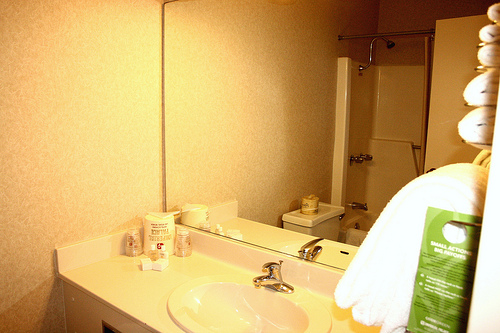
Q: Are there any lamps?
A: No, there are no lamps.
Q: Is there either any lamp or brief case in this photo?
A: No, there are no lamps or briefcases.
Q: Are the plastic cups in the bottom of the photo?
A: Yes, the cups are in the bottom of the image.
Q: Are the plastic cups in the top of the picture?
A: No, the cups are in the bottom of the image.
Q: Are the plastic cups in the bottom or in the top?
A: The cups are in the bottom of the image.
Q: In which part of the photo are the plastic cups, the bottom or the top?
A: The cups are in the bottom of the image.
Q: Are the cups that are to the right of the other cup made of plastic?
A: Yes, the cups are made of plastic.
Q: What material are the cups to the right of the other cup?
A: The cups are made of plastic.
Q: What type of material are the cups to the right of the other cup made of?
A: The cups are made of plastic.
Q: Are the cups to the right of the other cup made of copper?
A: No, the cups are made of plastic.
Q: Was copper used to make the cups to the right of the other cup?
A: No, the cups are made of plastic.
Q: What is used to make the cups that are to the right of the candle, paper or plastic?
A: The cups are made of plastic.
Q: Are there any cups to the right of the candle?
A: Yes, there are cups to the right of the candle.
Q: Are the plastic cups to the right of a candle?
A: Yes, the cups are to the right of a candle.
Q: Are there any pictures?
A: No, there are no pictures.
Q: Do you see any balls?
A: No, there are no balls.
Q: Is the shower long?
A: Yes, the shower is long.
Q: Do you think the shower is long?
A: Yes, the shower is long.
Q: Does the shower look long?
A: Yes, the shower is long.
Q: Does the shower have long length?
A: Yes, the shower is long.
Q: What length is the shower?
A: The shower is long.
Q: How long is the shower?
A: The shower is long.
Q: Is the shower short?
A: No, the shower is long.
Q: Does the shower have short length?
A: No, the shower is long.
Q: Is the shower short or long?
A: The shower is long.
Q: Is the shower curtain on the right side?
A: Yes, the shower curtain is on the right of the image.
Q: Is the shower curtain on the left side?
A: No, the shower curtain is on the right of the image.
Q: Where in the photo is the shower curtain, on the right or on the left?
A: The shower curtain is on the right of the image.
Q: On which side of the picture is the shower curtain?
A: The shower curtain is on the right of the image.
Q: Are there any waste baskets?
A: No, there are no waste baskets.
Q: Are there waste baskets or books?
A: No, there are no waste baskets or books.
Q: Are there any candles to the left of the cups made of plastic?
A: Yes, there is a candle to the left of the cups.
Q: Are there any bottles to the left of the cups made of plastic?
A: No, there is a candle to the left of the cups.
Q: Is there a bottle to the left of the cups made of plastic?
A: No, there is a candle to the left of the cups.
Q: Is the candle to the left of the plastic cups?
A: Yes, the candle is to the left of the cups.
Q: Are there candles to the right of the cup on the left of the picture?
A: Yes, there is a candle to the right of the cup.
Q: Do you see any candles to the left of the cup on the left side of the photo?
A: No, the candle is to the right of the cup.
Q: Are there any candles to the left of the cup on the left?
A: No, the candle is to the right of the cup.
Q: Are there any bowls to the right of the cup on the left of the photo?
A: No, there is a candle to the right of the cup.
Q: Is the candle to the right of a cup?
A: Yes, the candle is to the right of a cup.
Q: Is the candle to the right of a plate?
A: No, the candle is to the right of a cup.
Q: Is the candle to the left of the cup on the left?
A: No, the candle is to the right of the cup.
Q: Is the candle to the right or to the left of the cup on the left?
A: The candle is to the right of the cup.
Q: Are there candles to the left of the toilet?
A: Yes, there is a candle to the left of the toilet.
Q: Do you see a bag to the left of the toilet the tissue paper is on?
A: No, there is a candle to the left of the toilet.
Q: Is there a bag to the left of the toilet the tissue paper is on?
A: No, there is a candle to the left of the toilet.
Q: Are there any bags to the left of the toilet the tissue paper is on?
A: No, there is a candle to the left of the toilet.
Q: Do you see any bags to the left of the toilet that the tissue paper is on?
A: No, there is a candle to the left of the toilet.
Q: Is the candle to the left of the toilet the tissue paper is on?
A: Yes, the candle is to the left of the toilet.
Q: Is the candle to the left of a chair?
A: No, the candle is to the left of the toilet.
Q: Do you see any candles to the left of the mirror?
A: Yes, there is a candle to the left of the mirror.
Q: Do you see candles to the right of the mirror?
A: No, the candle is to the left of the mirror.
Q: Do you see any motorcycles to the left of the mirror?
A: No, there is a candle to the left of the mirror.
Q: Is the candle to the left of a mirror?
A: Yes, the candle is to the left of a mirror.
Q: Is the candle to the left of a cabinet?
A: No, the candle is to the left of a mirror.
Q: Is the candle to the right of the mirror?
A: No, the candle is to the left of the mirror.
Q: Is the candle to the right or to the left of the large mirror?
A: The candle is to the left of the mirror.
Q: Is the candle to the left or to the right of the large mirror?
A: The candle is to the left of the mirror.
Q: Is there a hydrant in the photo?
A: No, there are no fire hydrants.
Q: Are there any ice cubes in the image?
A: No, there are no ice cubes.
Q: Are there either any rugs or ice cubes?
A: No, there are no ice cubes or rugs.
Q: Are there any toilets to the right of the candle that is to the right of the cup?
A: Yes, there is a toilet to the right of the candle.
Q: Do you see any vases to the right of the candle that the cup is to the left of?
A: No, there is a toilet to the right of the candle.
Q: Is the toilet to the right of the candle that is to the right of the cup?
A: Yes, the toilet is to the right of the candle.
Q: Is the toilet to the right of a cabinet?
A: No, the toilet is to the right of the candle.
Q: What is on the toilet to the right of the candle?
A: The tissue paper is on the toilet.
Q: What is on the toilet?
A: The tissue paper is on the toilet.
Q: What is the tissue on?
A: The tissue is on the toilet.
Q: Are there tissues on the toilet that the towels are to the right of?
A: Yes, there is a tissue on the toilet.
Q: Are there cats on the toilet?
A: No, there is a tissue on the toilet.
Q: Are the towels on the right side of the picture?
A: Yes, the towels are on the right of the image.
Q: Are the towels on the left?
A: No, the towels are on the right of the image.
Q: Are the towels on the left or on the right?
A: The towels are on the right of the image.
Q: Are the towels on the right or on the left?
A: The towels are on the right of the image.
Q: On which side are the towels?
A: The towels are on the right of the image.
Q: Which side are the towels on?
A: The towels are on the right of the image.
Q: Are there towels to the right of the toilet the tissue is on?
A: Yes, there are towels to the right of the toilet.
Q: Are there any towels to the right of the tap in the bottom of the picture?
A: Yes, there are towels to the right of the tap.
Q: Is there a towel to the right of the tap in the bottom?
A: Yes, there are towels to the right of the tap.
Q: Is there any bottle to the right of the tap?
A: No, there are towels to the right of the tap.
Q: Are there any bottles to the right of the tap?
A: No, there are towels to the right of the tap.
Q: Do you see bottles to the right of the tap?
A: No, there are towels to the right of the tap.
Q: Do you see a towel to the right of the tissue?
A: Yes, there are towels to the right of the tissue.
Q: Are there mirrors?
A: Yes, there is a mirror.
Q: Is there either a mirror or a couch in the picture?
A: Yes, there is a mirror.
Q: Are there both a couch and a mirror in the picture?
A: No, there is a mirror but no couches.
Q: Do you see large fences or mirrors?
A: Yes, there is a large mirror.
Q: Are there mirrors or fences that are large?
A: Yes, the mirror is large.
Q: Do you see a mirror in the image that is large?
A: Yes, there is a large mirror.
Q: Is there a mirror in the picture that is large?
A: Yes, there is a mirror that is large.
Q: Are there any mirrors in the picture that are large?
A: Yes, there is a mirror that is large.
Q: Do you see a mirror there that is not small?
A: Yes, there is a large mirror.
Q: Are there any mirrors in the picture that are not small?
A: Yes, there is a large mirror.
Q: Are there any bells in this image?
A: No, there are no bells.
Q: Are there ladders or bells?
A: No, there are no bells or ladders.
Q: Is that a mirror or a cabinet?
A: That is a mirror.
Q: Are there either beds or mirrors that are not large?
A: No, there is a mirror but it is large.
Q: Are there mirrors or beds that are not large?
A: No, there is a mirror but it is large.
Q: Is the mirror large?
A: Yes, the mirror is large.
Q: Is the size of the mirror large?
A: Yes, the mirror is large.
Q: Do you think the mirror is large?
A: Yes, the mirror is large.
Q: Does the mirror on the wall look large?
A: Yes, the mirror is large.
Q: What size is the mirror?
A: The mirror is large.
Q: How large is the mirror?
A: The mirror is large.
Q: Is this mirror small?
A: No, the mirror is large.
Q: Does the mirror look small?
A: No, the mirror is large.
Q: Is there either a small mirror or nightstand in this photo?
A: No, there is a mirror but it is large.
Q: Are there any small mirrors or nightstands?
A: No, there is a mirror but it is large.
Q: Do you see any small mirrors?
A: No, there is a mirror but it is large.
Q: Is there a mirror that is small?
A: No, there is a mirror but it is large.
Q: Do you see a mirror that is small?
A: No, there is a mirror but it is large.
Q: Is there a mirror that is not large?
A: No, there is a mirror but it is large.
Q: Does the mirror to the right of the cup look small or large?
A: The mirror is large.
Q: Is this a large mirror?
A: Yes, this is a large mirror.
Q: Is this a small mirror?
A: No, this is a large mirror.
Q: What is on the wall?
A: The mirror is on the wall.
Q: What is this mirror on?
A: The mirror is on the wall.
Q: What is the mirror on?
A: The mirror is on the wall.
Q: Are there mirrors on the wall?
A: Yes, there is a mirror on the wall.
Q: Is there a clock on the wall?
A: No, there is a mirror on the wall.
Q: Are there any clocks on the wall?
A: No, there is a mirror on the wall.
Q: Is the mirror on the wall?
A: Yes, the mirror is on the wall.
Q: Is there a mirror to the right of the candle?
A: Yes, there is a mirror to the right of the candle.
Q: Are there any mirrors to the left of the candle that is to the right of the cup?
A: No, the mirror is to the right of the candle.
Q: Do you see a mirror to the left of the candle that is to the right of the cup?
A: No, the mirror is to the right of the candle.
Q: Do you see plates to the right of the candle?
A: No, there is a mirror to the right of the candle.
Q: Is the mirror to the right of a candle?
A: Yes, the mirror is to the right of a candle.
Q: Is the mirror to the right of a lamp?
A: No, the mirror is to the right of a candle.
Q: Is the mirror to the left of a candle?
A: No, the mirror is to the right of a candle.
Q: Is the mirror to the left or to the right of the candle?
A: The mirror is to the right of the candle.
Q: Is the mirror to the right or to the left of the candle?
A: The mirror is to the right of the candle.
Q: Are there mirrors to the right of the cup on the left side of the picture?
A: Yes, there is a mirror to the right of the cup.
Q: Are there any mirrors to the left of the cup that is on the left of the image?
A: No, the mirror is to the right of the cup.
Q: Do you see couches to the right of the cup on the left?
A: No, there is a mirror to the right of the cup.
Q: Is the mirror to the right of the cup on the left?
A: Yes, the mirror is to the right of the cup.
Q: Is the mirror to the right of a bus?
A: No, the mirror is to the right of the cup.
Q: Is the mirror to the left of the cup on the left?
A: No, the mirror is to the right of the cup.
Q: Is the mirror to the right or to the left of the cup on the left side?
A: The mirror is to the right of the cup.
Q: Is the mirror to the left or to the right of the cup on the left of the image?
A: The mirror is to the right of the cup.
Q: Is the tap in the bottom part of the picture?
A: Yes, the tap is in the bottom of the image.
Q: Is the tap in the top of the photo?
A: No, the tap is in the bottom of the image.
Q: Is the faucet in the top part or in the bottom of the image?
A: The faucet is in the bottom of the image.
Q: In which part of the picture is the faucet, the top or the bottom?
A: The faucet is in the bottom of the image.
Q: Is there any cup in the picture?
A: Yes, there is a cup.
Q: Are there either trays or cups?
A: Yes, there is a cup.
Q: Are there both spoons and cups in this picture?
A: No, there is a cup but no spoons.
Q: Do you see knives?
A: No, there are no knives.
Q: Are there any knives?
A: No, there are no knives.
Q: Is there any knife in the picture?
A: No, there are no knives.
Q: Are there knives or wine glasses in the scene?
A: No, there are no knives or wine glasses.